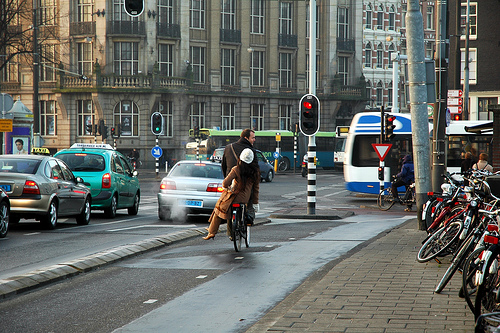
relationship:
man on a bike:
[220, 127, 258, 176] [228, 197, 255, 251]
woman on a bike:
[202, 146, 262, 246] [228, 197, 255, 251]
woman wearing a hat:
[202, 146, 262, 246] [238, 147, 256, 165]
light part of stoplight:
[301, 98, 313, 113] [299, 92, 321, 139]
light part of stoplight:
[155, 126, 161, 133] [149, 111, 164, 137]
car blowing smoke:
[157, 158, 227, 226] [167, 197, 191, 223]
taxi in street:
[50, 142, 142, 218] [1, 169, 410, 302]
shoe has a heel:
[202, 232, 217, 245] [210, 235, 217, 241]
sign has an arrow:
[150, 145, 164, 160] [153, 147, 161, 159]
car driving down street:
[157, 158, 227, 226] [1, 169, 410, 302]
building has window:
[1, 1, 358, 173] [187, 43, 208, 86]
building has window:
[1, 1, 358, 173] [219, 47, 238, 88]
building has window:
[1, 1, 358, 173] [249, 50, 267, 90]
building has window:
[1, 1, 358, 173] [278, 51, 296, 93]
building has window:
[1, 1, 358, 173] [155, 42, 174, 76]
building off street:
[1, 1, 358, 173] [1, 169, 410, 302]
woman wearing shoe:
[202, 146, 262, 246] [202, 232, 217, 245]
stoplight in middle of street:
[299, 92, 321, 139] [1, 169, 410, 302]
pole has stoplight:
[306, 144, 318, 205] [299, 92, 321, 139]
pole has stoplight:
[293, 133, 298, 160] [290, 122, 300, 137]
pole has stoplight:
[154, 137, 163, 175] [149, 111, 164, 137]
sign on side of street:
[371, 140, 394, 163] [1, 169, 410, 302]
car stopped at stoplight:
[157, 158, 227, 226] [299, 92, 321, 139]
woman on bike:
[202, 146, 262, 246] [228, 197, 255, 251]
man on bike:
[220, 127, 258, 176] [228, 197, 255, 251]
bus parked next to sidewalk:
[342, 110, 498, 201] [254, 215, 494, 331]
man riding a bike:
[220, 127, 258, 176] [228, 197, 255, 251]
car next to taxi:
[157, 158, 227, 226] [50, 142, 142, 218]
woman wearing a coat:
[202, 146, 262, 246] [220, 165, 261, 207]